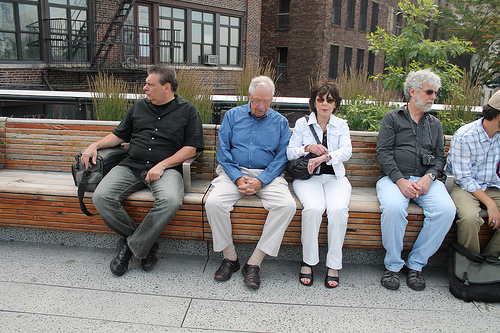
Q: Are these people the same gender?
A: No, they are both male and female.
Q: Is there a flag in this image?
A: No, there are no flags.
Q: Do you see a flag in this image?
A: No, there are no flags.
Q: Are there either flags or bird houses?
A: No, there are no flags or bird houses.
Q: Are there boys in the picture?
A: No, there are no boys.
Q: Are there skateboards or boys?
A: No, there are no boys or skateboards.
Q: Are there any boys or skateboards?
A: No, there are no boys or skateboards.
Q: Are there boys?
A: No, there are no boys.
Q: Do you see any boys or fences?
A: No, there are no boys or fences.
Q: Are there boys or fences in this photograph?
A: No, there are no boys or fences.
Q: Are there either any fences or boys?
A: No, there are no boys or fences.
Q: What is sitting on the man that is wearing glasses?
A: The shirt is sitting on the man.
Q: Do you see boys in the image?
A: No, there are no boys.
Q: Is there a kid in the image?
A: No, there are no children.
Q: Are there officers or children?
A: No, there are no children or officers.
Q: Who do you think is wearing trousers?
A: The man is wearing trousers.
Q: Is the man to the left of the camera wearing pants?
A: Yes, the man is wearing pants.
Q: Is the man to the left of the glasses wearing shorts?
A: No, the man is wearing pants.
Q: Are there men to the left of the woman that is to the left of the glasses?
A: Yes, there is a man to the left of the woman.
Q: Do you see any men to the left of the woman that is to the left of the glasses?
A: Yes, there is a man to the left of the woman.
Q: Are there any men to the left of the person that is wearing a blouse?
A: Yes, there is a man to the left of the woman.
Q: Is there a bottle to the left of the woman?
A: No, there is a man to the left of the woman.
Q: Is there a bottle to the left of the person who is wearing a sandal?
A: No, there is a man to the left of the woman.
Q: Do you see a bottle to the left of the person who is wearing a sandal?
A: No, there is a man to the left of the woman.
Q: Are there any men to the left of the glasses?
A: Yes, there is a man to the left of the glasses.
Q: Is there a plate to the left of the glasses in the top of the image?
A: No, there is a man to the left of the glasses.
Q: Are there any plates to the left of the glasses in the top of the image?
A: No, there is a man to the left of the glasses.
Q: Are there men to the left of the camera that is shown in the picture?
A: Yes, there is a man to the left of the camera.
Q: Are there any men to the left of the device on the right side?
A: Yes, there is a man to the left of the camera.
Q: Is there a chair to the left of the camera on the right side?
A: No, there is a man to the left of the camera.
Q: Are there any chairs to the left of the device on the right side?
A: No, there is a man to the left of the camera.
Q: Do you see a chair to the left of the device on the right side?
A: No, there is a man to the left of the camera.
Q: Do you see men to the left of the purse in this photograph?
A: Yes, there is a man to the left of the purse.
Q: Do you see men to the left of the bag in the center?
A: Yes, there is a man to the left of the purse.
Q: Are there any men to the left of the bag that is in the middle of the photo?
A: Yes, there is a man to the left of the purse.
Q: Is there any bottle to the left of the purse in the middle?
A: No, there is a man to the left of the purse.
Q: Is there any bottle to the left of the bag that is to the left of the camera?
A: No, there is a man to the left of the purse.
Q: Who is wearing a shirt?
A: The man is wearing a shirt.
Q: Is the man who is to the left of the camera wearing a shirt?
A: Yes, the man is wearing a shirt.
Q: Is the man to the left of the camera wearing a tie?
A: No, the man is wearing a shirt.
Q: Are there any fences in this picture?
A: No, there are no fences.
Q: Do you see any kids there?
A: No, there are no kids.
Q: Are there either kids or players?
A: No, there are no kids or players.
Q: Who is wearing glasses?
A: The man is wearing glasses.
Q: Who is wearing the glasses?
A: The man is wearing glasses.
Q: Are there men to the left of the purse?
A: Yes, there is a man to the left of the purse.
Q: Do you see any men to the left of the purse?
A: Yes, there is a man to the left of the purse.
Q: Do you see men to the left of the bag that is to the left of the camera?
A: Yes, there is a man to the left of the purse.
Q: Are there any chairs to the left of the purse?
A: No, there is a man to the left of the purse.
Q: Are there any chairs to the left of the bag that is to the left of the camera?
A: No, there is a man to the left of the purse.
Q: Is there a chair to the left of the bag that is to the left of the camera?
A: No, there is a man to the left of the purse.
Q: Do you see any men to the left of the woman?
A: Yes, there is a man to the left of the woman.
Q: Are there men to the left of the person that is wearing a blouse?
A: Yes, there is a man to the left of the woman.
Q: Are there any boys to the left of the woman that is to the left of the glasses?
A: No, there is a man to the left of the woman.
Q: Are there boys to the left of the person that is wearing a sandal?
A: No, there is a man to the left of the woman.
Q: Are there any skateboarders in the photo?
A: No, there are no skateboarders.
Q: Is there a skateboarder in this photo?
A: No, there are no skateboarders.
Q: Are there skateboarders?
A: No, there are no skateboarders.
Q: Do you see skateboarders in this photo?
A: No, there are no skateboarders.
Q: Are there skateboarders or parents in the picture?
A: No, there are no skateboarders or parents.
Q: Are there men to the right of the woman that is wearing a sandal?
A: Yes, there is a man to the right of the woman.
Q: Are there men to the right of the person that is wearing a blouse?
A: Yes, there is a man to the right of the woman.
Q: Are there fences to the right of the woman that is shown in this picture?
A: No, there is a man to the right of the woman.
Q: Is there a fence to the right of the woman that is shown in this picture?
A: No, there is a man to the right of the woman.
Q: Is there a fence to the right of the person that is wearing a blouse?
A: No, there is a man to the right of the woman.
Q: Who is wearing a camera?
A: The man is wearing a camera.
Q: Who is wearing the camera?
A: The man is wearing a camera.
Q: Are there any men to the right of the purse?
A: Yes, there is a man to the right of the purse.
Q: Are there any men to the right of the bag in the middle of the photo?
A: Yes, there is a man to the right of the purse.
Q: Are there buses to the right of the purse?
A: No, there is a man to the right of the purse.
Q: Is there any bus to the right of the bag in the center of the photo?
A: No, there is a man to the right of the purse.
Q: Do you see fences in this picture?
A: No, there are no fences.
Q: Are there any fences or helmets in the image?
A: No, there are no fences or helmets.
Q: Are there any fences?
A: No, there are no fences.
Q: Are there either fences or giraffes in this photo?
A: No, there are no fences or giraffes.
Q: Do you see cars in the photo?
A: No, there are no cars.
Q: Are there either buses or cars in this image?
A: No, there are no cars or buses.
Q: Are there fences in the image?
A: No, there are no fences.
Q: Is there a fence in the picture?
A: No, there are no fences.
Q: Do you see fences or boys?
A: No, there are no fences or boys.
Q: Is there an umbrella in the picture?
A: No, there are no umbrellas.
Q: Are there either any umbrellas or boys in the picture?
A: No, there are no umbrellas or boys.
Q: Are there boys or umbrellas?
A: No, there are no umbrellas or boys.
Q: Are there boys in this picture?
A: No, there are no boys.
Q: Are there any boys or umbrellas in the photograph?
A: No, there are no boys or umbrellas.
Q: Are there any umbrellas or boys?
A: No, there are no boys or umbrellas.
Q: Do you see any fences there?
A: No, there are no fences.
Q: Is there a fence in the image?
A: No, there are no fences.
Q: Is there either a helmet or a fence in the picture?
A: No, there are no fences or helmets.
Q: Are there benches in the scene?
A: Yes, there is a bench.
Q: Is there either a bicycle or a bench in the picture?
A: Yes, there is a bench.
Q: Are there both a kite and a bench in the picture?
A: No, there is a bench but no kites.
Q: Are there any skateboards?
A: No, there are no skateboards.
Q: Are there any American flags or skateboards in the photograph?
A: No, there are no skateboards or American flags.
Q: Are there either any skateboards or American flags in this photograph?
A: No, there are no skateboards or American flags.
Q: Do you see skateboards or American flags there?
A: No, there are no skateboards or American flags.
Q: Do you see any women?
A: Yes, there is a woman.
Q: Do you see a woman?
A: Yes, there is a woman.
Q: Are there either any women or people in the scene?
A: Yes, there is a woman.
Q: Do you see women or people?
A: Yes, there is a woman.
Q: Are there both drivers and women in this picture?
A: No, there is a woman but no drivers.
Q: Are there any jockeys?
A: No, there are no jockeys.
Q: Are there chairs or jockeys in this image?
A: No, there are no jockeys or chairs.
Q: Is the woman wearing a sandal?
A: Yes, the woman is wearing a sandal.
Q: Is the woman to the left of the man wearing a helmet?
A: No, the woman is wearing a sandal.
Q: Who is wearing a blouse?
A: The woman is wearing a blouse.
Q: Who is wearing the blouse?
A: The woman is wearing a blouse.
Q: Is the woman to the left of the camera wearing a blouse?
A: Yes, the woman is wearing a blouse.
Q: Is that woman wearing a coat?
A: No, the woman is wearing a blouse.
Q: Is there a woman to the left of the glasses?
A: Yes, there is a woman to the left of the glasses.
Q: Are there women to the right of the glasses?
A: No, the woman is to the left of the glasses.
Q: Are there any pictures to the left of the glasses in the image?
A: No, there is a woman to the left of the glasses.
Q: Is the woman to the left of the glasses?
A: Yes, the woman is to the left of the glasses.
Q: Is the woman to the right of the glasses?
A: No, the woman is to the left of the glasses.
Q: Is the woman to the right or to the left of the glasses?
A: The woman is to the left of the glasses.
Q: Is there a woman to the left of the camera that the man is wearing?
A: Yes, there is a woman to the left of the camera.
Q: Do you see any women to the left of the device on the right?
A: Yes, there is a woman to the left of the camera.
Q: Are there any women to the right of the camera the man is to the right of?
A: No, the woman is to the left of the camera.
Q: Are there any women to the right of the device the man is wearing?
A: No, the woman is to the left of the camera.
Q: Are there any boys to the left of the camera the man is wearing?
A: No, there is a woman to the left of the camera.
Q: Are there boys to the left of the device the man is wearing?
A: No, there is a woman to the left of the camera.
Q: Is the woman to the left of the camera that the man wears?
A: Yes, the woman is to the left of the camera.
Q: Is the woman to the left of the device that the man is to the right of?
A: Yes, the woman is to the left of the camera.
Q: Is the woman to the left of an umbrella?
A: No, the woman is to the left of the camera.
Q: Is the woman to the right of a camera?
A: No, the woman is to the left of a camera.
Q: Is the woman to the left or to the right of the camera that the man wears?
A: The woman is to the left of the camera.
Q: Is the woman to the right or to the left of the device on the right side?
A: The woman is to the left of the camera.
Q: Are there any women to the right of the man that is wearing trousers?
A: Yes, there is a woman to the right of the man.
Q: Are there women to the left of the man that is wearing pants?
A: No, the woman is to the right of the man.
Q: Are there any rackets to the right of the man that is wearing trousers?
A: No, there is a woman to the right of the man.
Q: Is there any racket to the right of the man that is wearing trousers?
A: No, there is a woman to the right of the man.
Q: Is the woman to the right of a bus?
A: No, the woman is to the right of a man.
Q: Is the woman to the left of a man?
A: No, the woman is to the right of a man.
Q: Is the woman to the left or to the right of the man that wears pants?
A: The woman is to the right of the man.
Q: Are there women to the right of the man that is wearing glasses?
A: Yes, there is a woman to the right of the man.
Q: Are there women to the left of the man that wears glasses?
A: No, the woman is to the right of the man.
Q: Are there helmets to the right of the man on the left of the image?
A: No, there is a woman to the right of the man.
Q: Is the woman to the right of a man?
A: Yes, the woman is to the right of a man.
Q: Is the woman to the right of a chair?
A: No, the woman is to the right of a man.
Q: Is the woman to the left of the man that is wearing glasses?
A: No, the woman is to the right of the man.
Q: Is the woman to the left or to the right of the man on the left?
A: The woman is to the right of the man.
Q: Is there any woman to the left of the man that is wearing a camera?
A: Yes, there is a woman to the left of the man.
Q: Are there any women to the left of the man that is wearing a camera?
A: Yes, there is a woman to the left of the man.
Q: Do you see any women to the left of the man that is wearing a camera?
A: Yes, there is a woman to the left of the man.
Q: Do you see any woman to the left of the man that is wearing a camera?
A: Yes, there is a woman to the left of the man.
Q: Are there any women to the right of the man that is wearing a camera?
A: No, the woman is to the left of the man.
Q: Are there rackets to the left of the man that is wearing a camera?
A: No, there is a woman to the left of the man.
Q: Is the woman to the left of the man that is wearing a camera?
A: Yes, the woman is to the left of the man.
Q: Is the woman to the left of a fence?
A: No, the woman is to the left of the man.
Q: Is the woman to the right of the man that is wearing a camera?
A: No, the woman is to the left of the man.